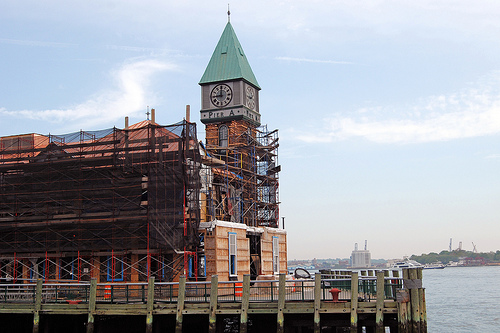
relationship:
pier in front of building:
[216, 257, 429, 331] [2, 4, 290, 298]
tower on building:
[198, 3, 262, 227] [2, 4, 290, 298]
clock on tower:
[209, 83, 234, 109] [198, 3, 262, 227]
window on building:
[228, 232, 238, 278] [2, 4, 290, 298]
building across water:
[350, 249, 373, 269] [420, 264, 499, 331]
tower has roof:
[198, 3, 262, 227] [198, 21, 263, 90]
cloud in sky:
[295, 86, 497, 147] [1, 0, 499, 259]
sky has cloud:
[1, 0, 499, 259] [295, 86, 497, 147]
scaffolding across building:
[176, 101, 289, 248] [2, 4, 290, 298]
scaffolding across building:
[206, 127, 282, 228] [2, 4, 290, 298]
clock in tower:
[209, 83, 234, 109] [198, 3, 262, 227]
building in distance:
[350, 249, 373, 269] [281, 183, 499, 270]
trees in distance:
[409, 249, 499, 263] [281, 183, 499, 270]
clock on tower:
[246, 85, 258, 108] [198, 3, 262, 227]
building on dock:
[2, 4, 290, 298] [1, 267, 429, 332]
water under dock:
[420, 264, 499, 331] [1, 267, 429, 332]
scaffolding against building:
[176, 101, 289, 248] [2, 4, 290, 298]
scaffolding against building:
[206, 127, 282, 228] [2, 4, 290, 298]